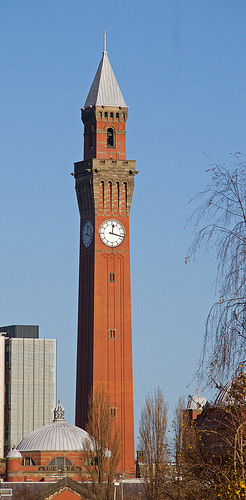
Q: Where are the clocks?
A: In the tower.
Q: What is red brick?
A: The building with the tower.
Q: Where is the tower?
A: In a city.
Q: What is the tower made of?
A: Brick.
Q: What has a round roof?
A: The building next to the tower.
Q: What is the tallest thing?
A: The tower.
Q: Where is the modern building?
A: Behind the brick building.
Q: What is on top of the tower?
A: A spire.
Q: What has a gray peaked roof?
A: The tower.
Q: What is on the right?
A: Tree.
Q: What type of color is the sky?
A: Blue.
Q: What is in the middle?
A: Clock tower.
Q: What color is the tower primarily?
A: Red.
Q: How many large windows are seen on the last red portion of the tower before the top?
A: Two.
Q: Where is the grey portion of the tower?
A: Top.